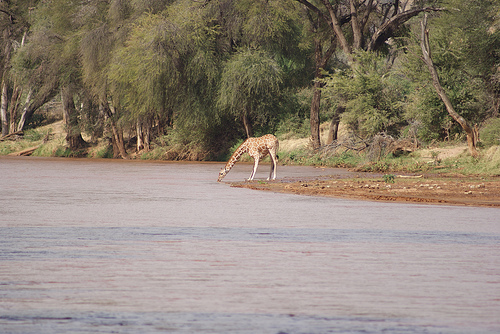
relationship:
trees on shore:
[12, 13, 232, 169] [7, 148, 496, 330]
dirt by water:
[229, 172, 365, 211] [173, 215, 375, 313]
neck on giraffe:
[223, 144, 249, 171] [213, 130, 284, 186]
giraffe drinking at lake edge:
[213, 130, 284, 186] [1, 142, 498, 204]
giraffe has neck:
[217, 133, 280, 183] [220, 143, 242, 173]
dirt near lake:
[0, 100, 497, 202] [2, 154, 498, 330]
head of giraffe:
[216, 168, 228, 182] [217, 131, 287, 189]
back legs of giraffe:
[268, 153, 275, 179] [217, 133, 280, 183]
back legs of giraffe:
[267, 146, 279, 179] [215, 133, 281, 185]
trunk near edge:
[113, 121, 123, 159] [3, 145, 427, 160]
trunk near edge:
[111, 140, 117, 155] [3, 145, 427, 160]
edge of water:
[3, 145, 427, 160] [6, 159, 498, 332]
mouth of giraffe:
[216, 168, 231, 183] [216, 131, 308, 189]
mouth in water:
[216, 168, 231, 183] [25, 160, 442, 312]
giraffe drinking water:
[217, 133, 280, 183] [11, 155, 478, 325]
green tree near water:
[107, 18, 215, 114] [15, 154, 442, 331]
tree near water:
[224, 56, 279, 130] [77, 200, 357, 317]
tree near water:
[238, 5, 336, 119] [6, 159, 498, 332]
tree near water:
[1, 28, 133, 160] [0, 165, 238, 311]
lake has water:
[0, 154, 498, 334] [138, 230, 450, 300]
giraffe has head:
[217, 133, 280, 183] [215, 168, 226, 185]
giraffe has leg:
[217, 133, 280, 183] [251, 155, 258, 185]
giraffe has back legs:
[217, 133, 280, 183] [267, 146, 279, 181]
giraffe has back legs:
[217, 133, 280, 183] [263, 157, 275, 179]